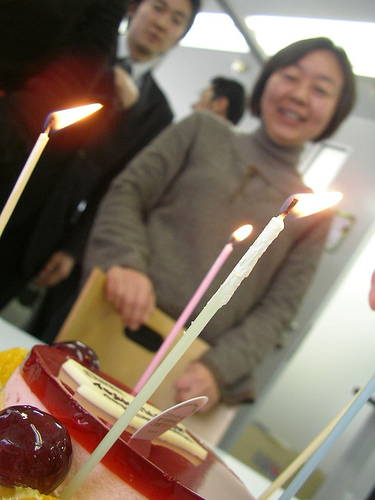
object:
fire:
[47, 106, 135, 129]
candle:
[225, 262, 242, 298]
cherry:
[0, 401, 72, 479]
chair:
[46, 266, 251, 458]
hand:
[105, 264, 156, 322]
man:
[0, 0, 195, 335]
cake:
[0, 333, 257, 499]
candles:
[200, 262, 219, 287]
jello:
[61, 358, 206, 459]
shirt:
[83, 110, 332, 403]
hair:
[247, 36, 359, 138]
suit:
[16, 34, 171, 296]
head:
[135, 16, 195, 59]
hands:
[174, 359, 221, 418]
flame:
[39, 98, 109, 141]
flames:
[274, 186, 347, 224]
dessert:
[62, 352, 207, 458]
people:
[83, 24, 358, 417]